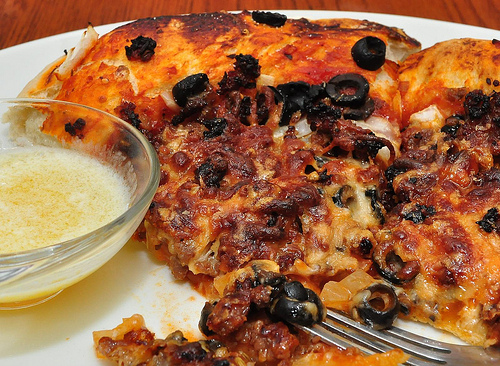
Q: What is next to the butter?
A: Slice of pizza.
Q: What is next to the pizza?
A: A glass bowl.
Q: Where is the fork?
A: In pizza.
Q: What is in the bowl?
A: Dipping sauce.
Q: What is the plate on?
A: Table.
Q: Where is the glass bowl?
A: On the plate.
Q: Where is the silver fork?
A: On pizza.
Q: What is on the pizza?
A: Black olives.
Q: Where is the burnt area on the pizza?
A: Top edge.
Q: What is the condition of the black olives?
A: Sliced.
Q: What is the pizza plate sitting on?
A: Brown table.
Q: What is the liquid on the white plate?
A: Grease from the cheese.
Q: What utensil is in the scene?
A: Fork.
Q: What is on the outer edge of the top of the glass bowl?
A: Protrusions used as handles.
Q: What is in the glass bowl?
A: Melted butter.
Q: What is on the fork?
A: Cheese and olive slice.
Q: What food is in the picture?
A: Pizza.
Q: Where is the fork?
A: In the lower right corner.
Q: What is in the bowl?
A: Butter.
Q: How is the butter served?
A: Melted.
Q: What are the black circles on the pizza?
A: Olives.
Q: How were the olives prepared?
A: Sliced.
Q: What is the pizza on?
A: The plate.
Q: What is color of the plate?
A: White.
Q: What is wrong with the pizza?
A: It's slightly burnt.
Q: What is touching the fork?
A: Olives.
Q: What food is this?
A: Pizza.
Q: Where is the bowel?
A: On the left.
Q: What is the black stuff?
A: Black olives.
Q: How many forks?
A: One.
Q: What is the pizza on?
A: Plate.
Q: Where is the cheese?
A: On the pizza.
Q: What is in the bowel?
A: Butter.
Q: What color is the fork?
A: Silver.